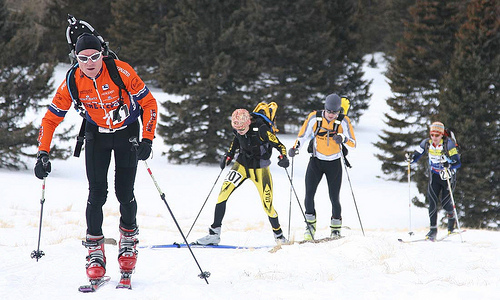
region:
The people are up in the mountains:
[26, 7, 486, 297]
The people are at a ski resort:
[25, 15, 456, 296]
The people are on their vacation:
[36, 17, 467, 297]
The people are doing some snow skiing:
[46, 18, 486, 296]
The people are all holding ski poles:
[10, 25, 478, 298]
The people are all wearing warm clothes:
[25, 6, 466, 289]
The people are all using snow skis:
[36, 12, 481, 292]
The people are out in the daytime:
[17, 10, 482, 296]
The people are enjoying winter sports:
[40, 12, 492, 278]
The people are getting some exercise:
[40, 13, 490, 293]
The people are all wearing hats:
[40, 15, 463, 296]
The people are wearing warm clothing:
[20, 3, 478, 279]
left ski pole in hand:
[153, 144, 212, 298]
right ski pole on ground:
[33, 160, 51, 265]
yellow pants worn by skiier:
[206, 166, 284, 213]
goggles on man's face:
[70, 47, 101, 57]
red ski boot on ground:
[117, 220, 139, 290]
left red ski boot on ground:
[80, 235, 105, 290]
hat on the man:
[322, 90, 338, 110]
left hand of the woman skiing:
[275, 151, 290, 166]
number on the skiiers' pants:
[225, 167, 240, 182]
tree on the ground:
[435, 0, 497, 232]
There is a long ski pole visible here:
[168, 222, 192, 260]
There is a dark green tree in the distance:
[454, 38, 482, 114]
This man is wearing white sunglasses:
[80, 48, 100, 81]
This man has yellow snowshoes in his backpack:
[255, 97, 285, 139]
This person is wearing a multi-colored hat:
[433, 119, 446, 143]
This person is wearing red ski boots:
[121, 215, 145, 297]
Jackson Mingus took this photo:
[78, 33, 271, 295]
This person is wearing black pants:
[332, 195, 344, 212]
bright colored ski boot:
[77, 226, 110, 282]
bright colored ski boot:
[111, 226, 147, 271]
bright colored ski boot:
[188, 213, 228, 250]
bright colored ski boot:
[263, 212, 290, 244]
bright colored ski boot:
[293, 210, 322, 240]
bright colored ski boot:
[323, 215, 342, 242]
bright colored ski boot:
[441, 213, 458, 232]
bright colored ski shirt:
[31, 54, 165, 152]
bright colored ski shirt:
[290, 108, 362, 165]